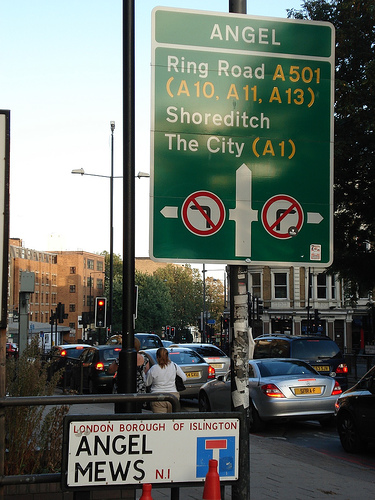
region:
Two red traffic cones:
[134, 453, 225, 499]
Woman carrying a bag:
[142, 347, 188, 398]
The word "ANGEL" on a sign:
[209, 17, 282, 51]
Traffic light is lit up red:
[89, 291, 111, 330]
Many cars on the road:
[47, 328, 372, 460]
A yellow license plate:
[288, 381, 325, 399]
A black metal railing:
[2, 389, 184, 498]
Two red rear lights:
[262, 374, 345, 402]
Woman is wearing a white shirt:
[138, 345, 188, 394]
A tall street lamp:
[67, 117, 150, 332]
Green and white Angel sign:
[150, 3, 335, 60]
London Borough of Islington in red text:
[72, 421, 237, 431]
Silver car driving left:
[199, 359, 343, 422]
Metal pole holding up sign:
[226, 263, 252, 498]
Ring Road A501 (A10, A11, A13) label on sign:
[164, 51, 324, 106]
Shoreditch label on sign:
[162, 102, 271, 132]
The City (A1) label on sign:
[162, 130, 298, 162]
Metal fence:
[0, 392, 181, 498]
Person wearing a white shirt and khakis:
[138, 348, 181, 412]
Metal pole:
[121, 1, 134, 416]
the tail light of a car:
[262, 380, 285, 402]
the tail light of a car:
[330, 375, 345, 400]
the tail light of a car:
[205, 364, 217, 379]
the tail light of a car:
[94, 360, 107, 373]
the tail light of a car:
[336, 360, 355, 377]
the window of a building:
[265, 269, 290, 302]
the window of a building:
[307, 271, 332, 302]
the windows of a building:
[86, 257, 107, 272]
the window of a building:
[66, 264, 78, 276]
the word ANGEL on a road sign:
[152, 4, 342, 66]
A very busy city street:
[115, 304, 352, 416]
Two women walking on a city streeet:
[100, 324, 182, 412]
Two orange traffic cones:
[143, 444, 231, 499]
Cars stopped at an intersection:
[68, 292, 348, 430]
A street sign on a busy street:
[162, 71, 329, 272]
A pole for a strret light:
[113, 285, 142, 394]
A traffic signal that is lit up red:
[89, 287, 110, 333]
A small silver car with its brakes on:
[193, 351, 329, 440]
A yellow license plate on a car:
[284, 377, 324, 396]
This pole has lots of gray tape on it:
[230, 291, 253, 399]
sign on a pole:
[128, 3, 342, 273]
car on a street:
[256, 360, 331, 415]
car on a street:
[285, 318, 335, 348]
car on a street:
[324, 391, 369, 428]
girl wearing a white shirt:
[151, 345, 183, 390]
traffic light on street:
[90, 287, 105, 328]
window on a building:
[263, 262, 289, 307]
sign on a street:
[55, 413, 246, 493]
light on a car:
[258, 377, 280, 411]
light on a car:
[321, 377, 345, 393]